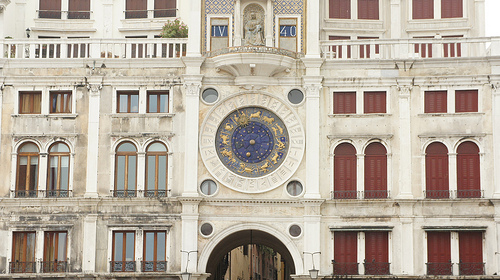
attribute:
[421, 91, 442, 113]
window — red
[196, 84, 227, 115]
circle — small, glass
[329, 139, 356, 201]
window — red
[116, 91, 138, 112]
window — small, square, glass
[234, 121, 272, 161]
design — blue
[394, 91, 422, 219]
wall — white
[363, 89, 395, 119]
window — red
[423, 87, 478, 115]
window — red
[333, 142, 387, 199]
windows — red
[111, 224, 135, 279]
window — tall , glass 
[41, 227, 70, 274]
window — glass